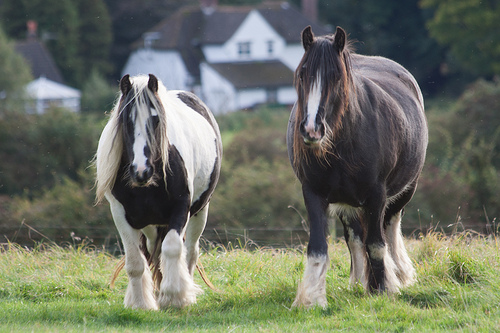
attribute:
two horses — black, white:
[87, 25, 429, 314]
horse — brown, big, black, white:
[287, 25, 429, 311]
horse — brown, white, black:
[84, 72, 223, 310]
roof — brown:
[132, 5, 328, 85]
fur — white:
[90, 73, 215, 313]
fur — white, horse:
[290, 208, 417, 313]